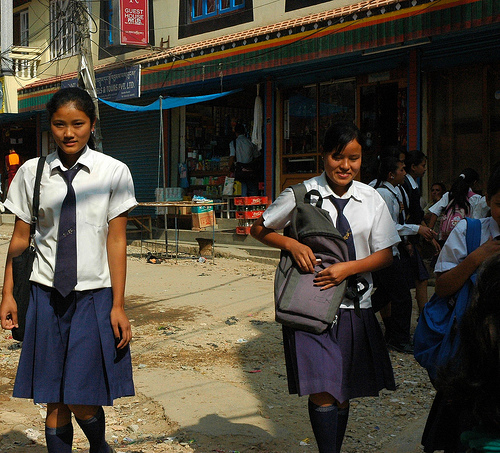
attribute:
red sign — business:
[114, 1, 155, 51]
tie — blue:
[52, 165, 82, 295]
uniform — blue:
[10, 147, 138, 413]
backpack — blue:
[278, 181, 350, 337]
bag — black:
[18, 148, 40, 345]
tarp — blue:
[92, 87, 235, 116]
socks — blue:
[273, 385, 416, 450]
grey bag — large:
[273, 184, 352, 334]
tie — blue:
[328, 195, 363, 308]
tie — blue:
[50, 164, 82, 302]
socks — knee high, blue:
[308, 402, 356, 450]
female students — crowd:
[0, 79, 494, 451]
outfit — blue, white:
[1, 145, 141, 407]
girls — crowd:
[358, 151, 497, 320]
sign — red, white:
[114, 0, 154, 47]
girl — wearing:
[265, 130, 392, 449]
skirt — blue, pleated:
[0, 283, 140, 410]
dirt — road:
[147, 251, 266, 451]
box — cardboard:
[191, 203, 222, 233]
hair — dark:
[47, 87, 94, 125]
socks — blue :
[309, 396, 349, 450]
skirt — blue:
[10, 290, 137, 405]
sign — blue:
[103, 55, 181, 139]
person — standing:
[225, 109, 261, 189]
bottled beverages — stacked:
[233, 194, 262, 238]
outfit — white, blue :
[260, 184, 394, 399]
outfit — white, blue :
[6, 149, 132, 399]